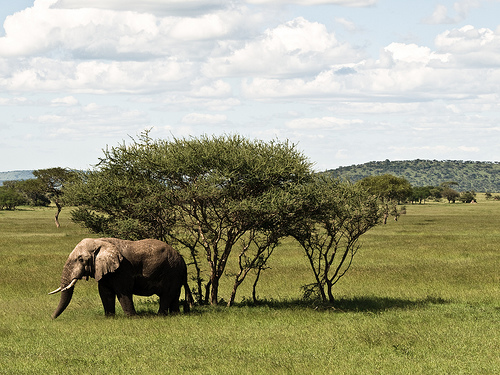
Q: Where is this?
A: This is at the field.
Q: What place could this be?
A: It is a field.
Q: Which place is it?
A: It is a field.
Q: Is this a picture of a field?
A: Yes, it is showing a field.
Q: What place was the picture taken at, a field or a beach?
A: It was taken at a field.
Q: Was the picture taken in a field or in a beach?
A: It was taken at a field.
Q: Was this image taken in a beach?
A: No, the picture was taken in a field.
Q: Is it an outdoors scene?
A: Yes, it is outdoors.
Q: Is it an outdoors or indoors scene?
A: It is outdoors.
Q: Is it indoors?
A: No, it is outdoors.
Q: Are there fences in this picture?
A: No, there are no fences.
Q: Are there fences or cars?
A: No, there are no fences or cars.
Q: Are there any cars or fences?
A: No, there are no fences or cars.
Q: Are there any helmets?
A: No, there are no helmets.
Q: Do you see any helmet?
A: No, there are no helmets.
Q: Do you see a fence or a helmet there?
A: No, there are no helmets or fences.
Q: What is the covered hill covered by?
A: The hill is covered by the tree.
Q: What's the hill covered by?
A: The hill is covered by the tree.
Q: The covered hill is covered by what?
A: The hill is covered by the tree.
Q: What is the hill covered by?
A: The hill is covered by the tree.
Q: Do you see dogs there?
A: No, there are no dogs.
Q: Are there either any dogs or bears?
A: No, there are no dogs or bears.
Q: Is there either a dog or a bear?
A: No, there are no dogs or bears.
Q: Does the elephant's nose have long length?
A: Yes, the nose is long.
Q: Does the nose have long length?
A: Yes, the nose is long.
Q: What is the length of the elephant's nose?
A: The nose is long.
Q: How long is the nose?
A: The nose is long.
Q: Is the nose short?
A: No, the nose is long.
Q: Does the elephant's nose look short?
A: No, the nose is long.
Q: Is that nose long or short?
A: The nose is long.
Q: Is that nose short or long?
A: The nose is long.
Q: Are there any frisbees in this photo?
A: No, there are no frisbees.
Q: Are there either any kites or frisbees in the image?
A: No, there are no frisbees or kites.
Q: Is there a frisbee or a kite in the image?
A: No, there are no frisbees or kites.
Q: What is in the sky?
A: The clouds are in the sky.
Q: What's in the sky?
A: The clouds are in the sky.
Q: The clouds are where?
A: The clouds are in the sky.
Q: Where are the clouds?
A: The clouds are in the sky.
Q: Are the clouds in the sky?
A: Yes, the clouds are in the sky.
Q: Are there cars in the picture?
A: No, there are no cars.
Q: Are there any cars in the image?
A: No, there are no cars.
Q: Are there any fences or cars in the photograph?
A: No, there are no cars or fences.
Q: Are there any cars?
A: No, there are no cars.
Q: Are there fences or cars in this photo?
A: No, there are no cars or fences.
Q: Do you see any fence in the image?
A: No, there are no fences.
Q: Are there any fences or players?
A: No, there are no fences or players.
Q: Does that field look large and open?
A: Yes, the field is large and open.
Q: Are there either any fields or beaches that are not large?
A: No, there is a field but it is large.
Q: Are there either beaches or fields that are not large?
A: No, there is a field but it is large.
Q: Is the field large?
A: Yes, the field is large.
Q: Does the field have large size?
A: Yes, the field is large.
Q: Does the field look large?
A: Yes, the field is large.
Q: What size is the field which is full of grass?
A: The field is large.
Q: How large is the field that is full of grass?
A: The field is large.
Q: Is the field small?
A: No, the field is large.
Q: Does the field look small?
A: No, the field is large.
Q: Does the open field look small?
A: No, the field is large.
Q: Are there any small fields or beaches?
A: No, there is a field but it is large.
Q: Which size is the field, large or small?
A: The field is large.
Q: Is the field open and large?
A: Yes, the field is open and large.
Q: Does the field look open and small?
A: No, the field is open but large.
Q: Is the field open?
A: Yes, the field is open.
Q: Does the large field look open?
A: Yes, the field is open.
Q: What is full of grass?
A: The field is full of grass.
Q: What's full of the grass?
A: The field is full of grass.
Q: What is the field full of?
A: The field is full of grass.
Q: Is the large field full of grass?
A: Yes, the field is full of grass.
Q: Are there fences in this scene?
A: No, there are no fences.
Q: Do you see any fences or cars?
A: No, there are no fences or cars.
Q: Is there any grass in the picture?
A: Yes, there is grass.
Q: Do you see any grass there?
A: Yes, there is grass.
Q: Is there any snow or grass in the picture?
A: Yes, there is grass.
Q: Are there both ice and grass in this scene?
A: No, there is grass but no ice.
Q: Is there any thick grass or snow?
A: Yes, there is thick grass.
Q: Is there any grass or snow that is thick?
A: Yes, the grass is thick.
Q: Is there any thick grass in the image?
A: Yes, there is thick grass.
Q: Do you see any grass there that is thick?
A: Yes, there is grass that is thick.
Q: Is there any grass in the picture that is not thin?
A: Yes, there is thick grass.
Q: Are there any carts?
A: No, there are no carts.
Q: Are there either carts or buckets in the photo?
A: No, there are no carts or buckets.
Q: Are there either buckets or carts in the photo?
A: No, there are no carts or buckets.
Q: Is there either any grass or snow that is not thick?
A: No, there is grass but it is thick.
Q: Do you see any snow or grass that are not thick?
A: No, there is grass but it is thick.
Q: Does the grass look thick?
A: Yes, the grass is thick.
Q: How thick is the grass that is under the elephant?
A: The grass is thick.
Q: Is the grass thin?
A: No, the grass is thick.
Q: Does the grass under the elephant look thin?
A: No, the grass is thick.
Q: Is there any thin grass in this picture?
A: No, there is grass but it is thick.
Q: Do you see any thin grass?
A: No, there is grass but it is thick.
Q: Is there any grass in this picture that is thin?
A: No, there is grass but it is thick.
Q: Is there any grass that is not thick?
A: No, there is grass but it is thick.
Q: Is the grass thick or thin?
A: The grass is thick.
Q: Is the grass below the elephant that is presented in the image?
A: Yes, the grass is below the elephant.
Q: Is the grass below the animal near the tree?
A: Yes, the grass is below the elephant.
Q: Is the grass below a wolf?
A: No, the grass is below the elephant.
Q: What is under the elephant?
A: The grass is under the elephant.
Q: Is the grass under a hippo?
A: No, the grass is under the elephant.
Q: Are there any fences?
A: No, there are no fences.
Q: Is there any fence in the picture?
A: No, there are no fences.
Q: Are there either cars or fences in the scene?
A: No, there are no fences or cars.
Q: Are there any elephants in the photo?
A: Yes, there is an elephant.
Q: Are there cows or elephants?
A: Yes, there is an elephant.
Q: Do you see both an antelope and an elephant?
A: No, there is an elephant but no antelopes.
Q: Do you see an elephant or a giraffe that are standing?
A: Yes, the elephant is standing.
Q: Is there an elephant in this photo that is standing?
A: Yes, there is an elephant that is standing.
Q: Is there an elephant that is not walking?
A: Yes, there is an elephant that is standing.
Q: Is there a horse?
A: No, there are no horses.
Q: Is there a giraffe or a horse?
A: No, there are no horses or giraffes.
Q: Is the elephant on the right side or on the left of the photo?
A: The elephant is on the left of the image.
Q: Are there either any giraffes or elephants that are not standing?
A: No, there is an elephant but it is standing.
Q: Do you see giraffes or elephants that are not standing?
A: No, there is an elephant but it is standing.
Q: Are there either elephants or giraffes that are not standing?
A: No, there is an elephant but it is standing.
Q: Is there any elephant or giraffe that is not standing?
A: No, there is an elephant but it is standing.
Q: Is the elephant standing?
A: Yes, the elephant is standing.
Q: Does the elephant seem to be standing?
A: Yes, the elephant is standing.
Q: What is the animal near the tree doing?
A: The elephant is standing.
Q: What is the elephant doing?
A: The elephant is standing.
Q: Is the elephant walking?
A: No, the elephant is standing.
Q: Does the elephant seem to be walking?
A: No, the elephant is standing.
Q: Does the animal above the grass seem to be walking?
A: No, the elephant is standing.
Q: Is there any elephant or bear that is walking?
A: No, there is an elephant but it is standing.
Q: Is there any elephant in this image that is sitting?
A: No, there is an elephant but it is standing.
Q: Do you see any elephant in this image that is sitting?
A: No, there is an elephant but it is standing.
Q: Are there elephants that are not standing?
A: No, there is an elephant but it is standing.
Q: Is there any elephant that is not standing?
A: No, there is an elephant but it is standing.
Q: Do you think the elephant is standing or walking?
A: The elephant is standing.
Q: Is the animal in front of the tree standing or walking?
A: The elephant is standing.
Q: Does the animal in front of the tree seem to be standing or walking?
A: The elephant is standing.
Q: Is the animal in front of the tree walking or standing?
A: The elephant is standing.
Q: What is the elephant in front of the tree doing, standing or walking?
A: The elephant is standing.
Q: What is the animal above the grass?
A: The animal is an elephant.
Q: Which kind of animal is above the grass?
A: The animal is an elephant.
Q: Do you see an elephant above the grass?
A: Yes, there is an elephant above the grass.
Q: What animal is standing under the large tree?
A: The elephant is standing under the tree.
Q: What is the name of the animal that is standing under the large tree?
A: The animal is an elephant.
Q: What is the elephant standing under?
A: The elephant is standing under the tree.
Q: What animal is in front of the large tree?
A: The elephant is in front of the tree.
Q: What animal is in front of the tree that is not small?
A: The animal is an elephant.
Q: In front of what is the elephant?
A: The elephant is in front of the tree.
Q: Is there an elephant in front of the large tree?
A: Yes, there is an elephant in front of the tree.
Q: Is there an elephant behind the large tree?
A: No, the elephant is in front of the tree.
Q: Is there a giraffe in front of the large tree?
A: No, there is an elephant in front of the tree.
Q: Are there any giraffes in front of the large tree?
A: No, there is an elephant in front of the tree.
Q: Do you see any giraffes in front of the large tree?
A: No, there is an elephant in front of the tree.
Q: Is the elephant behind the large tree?
A: No, the elephant is in front of the tree.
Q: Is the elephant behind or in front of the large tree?
A: The elephant is in front of the tree.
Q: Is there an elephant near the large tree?
A: Yes, there is an elephant near the tree.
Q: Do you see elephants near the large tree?
A: Yes, there is an elephant near the tree.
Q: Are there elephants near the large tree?
A: Yes, there is an elephant near the tree.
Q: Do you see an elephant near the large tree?
A: Yes, there is an elephant near the tree.